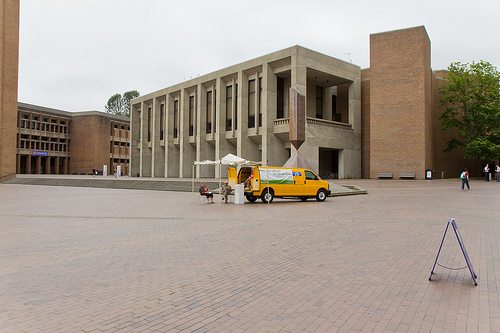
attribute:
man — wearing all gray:
[219, 180, 231, 203]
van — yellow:
[219, 155, 335, 215]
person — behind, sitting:
[219, 180, 231, 204]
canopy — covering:
[189, 150, 266, 205]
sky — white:
[23, 2, 499, 118]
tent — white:
[188, 153, 253, 200]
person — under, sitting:
[198, 180, 216, 203]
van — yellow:
[232, 163, 332, 204]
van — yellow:
[233, 158, 344, 221]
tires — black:
[257, 190, 332, 208]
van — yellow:
[241, 150, 336, 203]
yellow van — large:
[225, 157, 332, 206]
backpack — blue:
[458, 173, 465, 178]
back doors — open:
[213, 154, 270, 215]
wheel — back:
[262, 187, 274, 202]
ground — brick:
[14, 164, 484, 330]